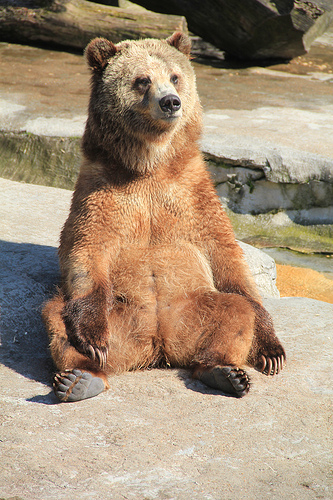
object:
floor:
[29, 418, 237, 497]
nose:
[159, 93, 182, 116]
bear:
[41, 31, 286, 403]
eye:
[132, 73, 152, 94]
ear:
[83, 36, 117, 72]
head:
[83, 30, 196, 135]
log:
[0, 1, 189, 66]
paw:
[60, 294, 111, 369]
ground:
[0, 0, 333, 498]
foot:
[52, 368, 111, 403]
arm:
[57, 184, 119, 371]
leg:
[41, 289, 144, 402]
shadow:
[0, 237, 89, 405]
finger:
[95, 347, 102, 367]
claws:
[88, 344, 96, 361]